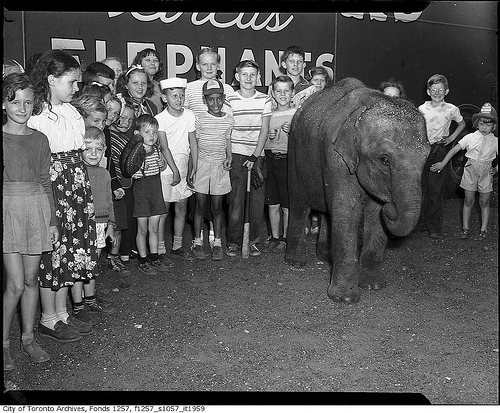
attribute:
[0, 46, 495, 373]
children — together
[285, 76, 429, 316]
elephant — baby, small, grey, dark, young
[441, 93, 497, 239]
girl — dark haired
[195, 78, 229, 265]
boy — cap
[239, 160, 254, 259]
bat — wooden, held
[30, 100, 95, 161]
shirt — white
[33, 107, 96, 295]
dress — floral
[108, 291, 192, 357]
snow — white